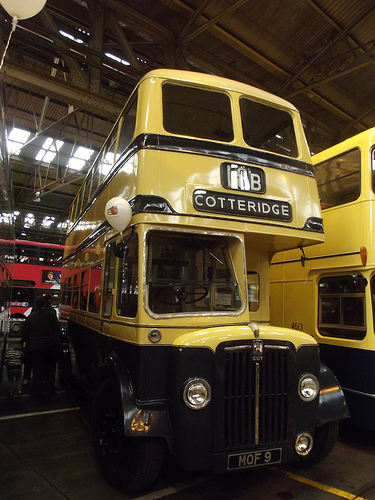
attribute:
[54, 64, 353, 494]
bus — parked, yellow, black, double decker, big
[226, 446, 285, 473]
license plate — black, silver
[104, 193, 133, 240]
balloon — white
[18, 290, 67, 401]
people — standing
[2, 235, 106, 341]
bus — red, parked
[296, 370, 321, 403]
headlight — round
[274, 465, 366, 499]
line — yellow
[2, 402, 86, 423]
line — white